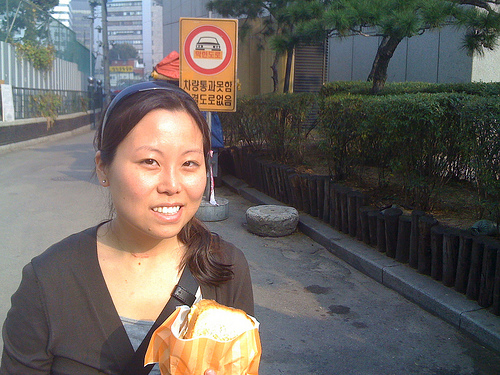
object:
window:
[121, 31, 124, 35]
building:
[0, 0, 209, 113]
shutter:
[298, 34, 330, 89]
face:
[100, 95, 211, 245]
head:
[94, 84, 210, 239]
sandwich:
[177, 291, 254, 349]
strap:
[163, 267, 195, 297]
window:
[135, 8, 142, 15]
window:
[98, 16, 104, 22]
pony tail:
[178, 219, 233, 285]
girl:
[5, 81, 270, 375]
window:
[128, 9, 134, 18]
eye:
[135, 158, 160, 167]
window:
[128, 21, 132, 25]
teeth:
[163, 207, 167, 213]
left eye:
[182, 158, 201, 171]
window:
[107, 29, 112, 32]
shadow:
[307, 282, 348, 319]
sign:
[178, 15, 239, 113]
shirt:
[8, 223, 261, 375]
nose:
[151, 165, 184, 195]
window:
[107, 10, 113, 15]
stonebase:
[246, 192, 306, 240]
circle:
[186, 27, 231, 75]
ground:
[0, 137, 495, 373]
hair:
[103, 88, 232, 295]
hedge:
[228, 93, 497, 185]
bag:
[145, 297, 265, 374]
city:
[2, 0, 499, 372]